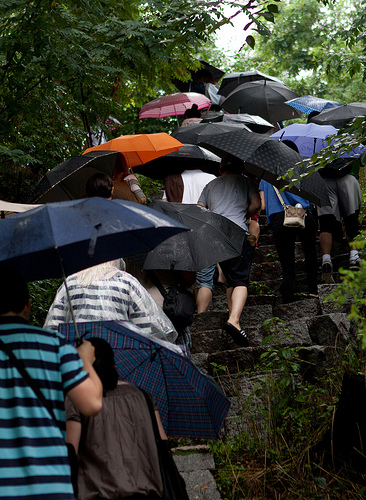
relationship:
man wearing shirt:
[187, 157, 265, 285] [195, 173, 256, 234]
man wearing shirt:
[0, 274, 104, 500] [11, 332, 60, 499]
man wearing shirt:
[0, 274, 104, 500] [0, 314, 90, 498]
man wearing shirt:
[16, 308, 88, 452] [192, 174, 273, 234]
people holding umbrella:
[65, 337, 170, 500] [55, 320, 232, 442]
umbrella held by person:
[2, 195, 190, 338] [0, 274, 106, 498]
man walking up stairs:
[197, 157, 261, 346] [200, 245, 337, 415]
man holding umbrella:
[197, 157, 261, 346] [220, 77, 302, 124]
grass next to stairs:
[208, 275, 363, 498] [202, 275, 356, 461]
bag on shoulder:
[153, 274, 195, 325] [153, 278, 174, 299]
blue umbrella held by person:
[270, 121, 365, 159] [267, 143, 319, 301]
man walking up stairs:
[197, 157, 261, 346] [165, 214, 356, 488]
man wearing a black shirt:
[0, 274, 104, 500] [0, 316, 89, 500]